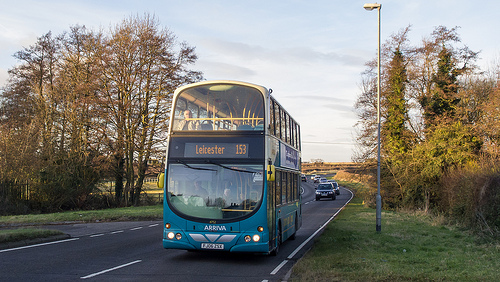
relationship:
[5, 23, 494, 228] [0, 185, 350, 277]
trees on side of road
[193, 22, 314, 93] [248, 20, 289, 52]
cloud in sky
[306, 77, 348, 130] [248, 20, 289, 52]
cloud in sky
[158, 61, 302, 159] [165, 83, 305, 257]
level on bus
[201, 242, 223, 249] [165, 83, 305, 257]
licence on bus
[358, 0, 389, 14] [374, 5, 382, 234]
light on post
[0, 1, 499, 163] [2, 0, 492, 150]
sky with clouds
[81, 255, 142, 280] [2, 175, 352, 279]
line on street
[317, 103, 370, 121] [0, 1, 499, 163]
clouds in sky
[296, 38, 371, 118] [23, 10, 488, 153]
clouds in sky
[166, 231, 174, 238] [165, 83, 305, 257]
headlight on bus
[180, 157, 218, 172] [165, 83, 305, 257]
wiper on bus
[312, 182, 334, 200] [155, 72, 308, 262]
car behind bus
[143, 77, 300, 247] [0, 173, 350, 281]
bus on road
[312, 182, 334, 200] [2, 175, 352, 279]
car on street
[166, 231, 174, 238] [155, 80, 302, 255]
headlight on bus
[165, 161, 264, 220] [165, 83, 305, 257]
front windshield on bus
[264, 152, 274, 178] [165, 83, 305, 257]
mirror on bus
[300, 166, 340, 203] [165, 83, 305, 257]
traffic behind bus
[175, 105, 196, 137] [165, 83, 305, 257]
man riding bus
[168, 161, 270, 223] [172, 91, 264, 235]
window on front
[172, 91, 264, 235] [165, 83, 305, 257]
front of bus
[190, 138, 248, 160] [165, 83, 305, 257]
bus sign on bus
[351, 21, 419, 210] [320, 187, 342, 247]
trees on side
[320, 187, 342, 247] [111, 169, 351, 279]
side of road